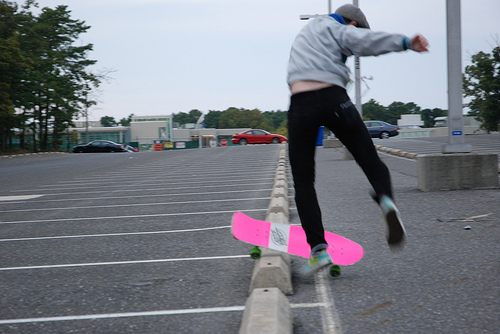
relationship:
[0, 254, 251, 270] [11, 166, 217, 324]
line on pavement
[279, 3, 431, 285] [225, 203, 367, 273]
skater falling off skateboard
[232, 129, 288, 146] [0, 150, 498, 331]
pavement car parked in parking lot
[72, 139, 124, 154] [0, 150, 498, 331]
car parked in parking lot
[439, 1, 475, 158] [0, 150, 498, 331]
concrete pole in middle of parking lot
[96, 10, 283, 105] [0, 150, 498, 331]
sky above parking lot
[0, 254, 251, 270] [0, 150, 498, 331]
line in parking lot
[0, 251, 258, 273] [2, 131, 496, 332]
line in parking lot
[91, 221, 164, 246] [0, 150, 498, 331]
line in parking lot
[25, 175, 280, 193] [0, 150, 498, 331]
line in parking lot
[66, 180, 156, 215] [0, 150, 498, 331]
line in parking lot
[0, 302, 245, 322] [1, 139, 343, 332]
line in parking lot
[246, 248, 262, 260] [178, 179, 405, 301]
green wheel of a skateboard